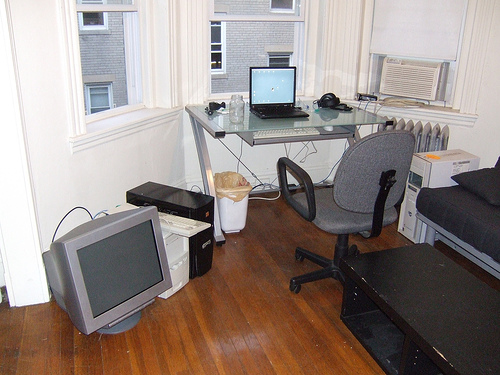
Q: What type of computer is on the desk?
A: Laptop.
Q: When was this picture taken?
A: Daytime.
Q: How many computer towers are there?
A: Three.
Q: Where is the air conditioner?
A: Right window.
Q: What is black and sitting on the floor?
A: Trunk.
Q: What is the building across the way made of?
A: Brick.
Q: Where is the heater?
A: Below the air conditioner.